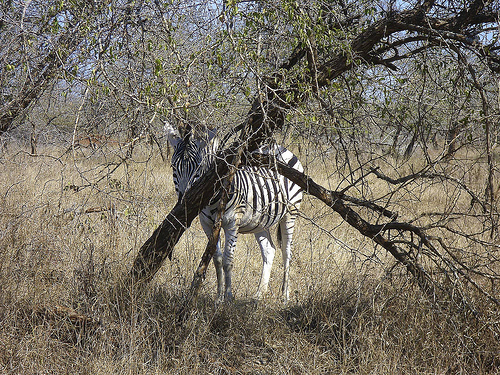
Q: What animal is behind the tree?
A: A black and white striped zebra.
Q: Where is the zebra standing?
A: Behind a tree.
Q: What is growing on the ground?
A: Dry brown brush.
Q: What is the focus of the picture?
A: One striped white zebra.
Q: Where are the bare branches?
A: Growing from a tree.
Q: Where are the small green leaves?
A: On a tree.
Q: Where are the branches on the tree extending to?
A: The ground.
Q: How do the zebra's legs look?
A: Mostly white.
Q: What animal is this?
A: A black and white zebra.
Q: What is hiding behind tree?
A: Zebra.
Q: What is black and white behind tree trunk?
A: Zebra.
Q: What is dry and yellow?
A: Grass.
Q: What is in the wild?
A: Zebra.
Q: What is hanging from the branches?
A: Leaves.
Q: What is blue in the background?
A: Sky.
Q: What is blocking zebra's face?
A: Tree trunk.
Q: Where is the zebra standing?
A: On dry grass.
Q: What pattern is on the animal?
A: Stripes.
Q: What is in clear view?
A: Zebra legs.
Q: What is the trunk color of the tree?
A: Brown.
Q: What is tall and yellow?
A: The grass is.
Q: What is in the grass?
A: The zebra is.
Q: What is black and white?
A: The zebra is.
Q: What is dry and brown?
A: The grass is.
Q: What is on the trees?
A: The green leaves.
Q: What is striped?
A: The zebra is.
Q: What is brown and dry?
A: The grass is.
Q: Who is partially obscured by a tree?
A: A zebra.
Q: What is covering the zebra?
A: Stripes.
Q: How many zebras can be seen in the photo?
A: One.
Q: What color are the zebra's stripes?
A: Black and White.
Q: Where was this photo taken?
A: Grasslands.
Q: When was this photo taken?
A: Daytime.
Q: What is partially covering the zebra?
A: A tree.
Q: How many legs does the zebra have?
A: Four.